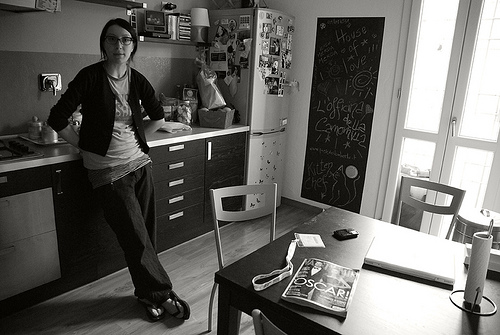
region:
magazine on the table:
[286, 242, 358, 319]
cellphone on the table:
[332, 220, 357, 244]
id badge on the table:
[241, 221, 330, 298]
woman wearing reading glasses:
[100, 30, 141, 57]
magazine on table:
[268, 240, 370, 334]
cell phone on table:
[327, 213, 373, 253]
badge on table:
[256, 219, 338, 304]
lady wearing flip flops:
[130, 266, 201, 332]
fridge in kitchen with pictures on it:
[210, 0, 320, 222]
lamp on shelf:
[188, 1, 221, 46]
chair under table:
[196, 166, 304, 279]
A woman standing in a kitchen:
[0, 0, 496, 333]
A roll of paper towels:
[460, 227, 495, 309]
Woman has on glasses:
[92, 12, 137, 67]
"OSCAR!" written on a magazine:
[290, 270, 350, 301]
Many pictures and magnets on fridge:
[201, 6, 292, 101]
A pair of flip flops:
[140, 285, 195, 325]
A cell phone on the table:
[325, 220, 360, 245]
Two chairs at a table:
[200, 170, 495, 330]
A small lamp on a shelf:
[185, 0, 215, 50]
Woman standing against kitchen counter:
[50, 15, 189, 326]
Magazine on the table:
[280, 253, 361, 323]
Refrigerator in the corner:
[196, 2, 300, 217]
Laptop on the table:
[360, 225, 468, 293]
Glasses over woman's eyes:
[100, 32, 136, 49]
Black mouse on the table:
[333, 227, 360, 241]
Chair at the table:
[395, 174, 465, 239]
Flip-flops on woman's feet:
[143, 294, 198, 323]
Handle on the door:
[446, 113, 460, 144]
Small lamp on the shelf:
[190, 4, 212, 43]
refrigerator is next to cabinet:
[204, 8, 295, 212]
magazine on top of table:
[213, 205, 498, 334]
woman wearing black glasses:
[45, 18, 192, 323]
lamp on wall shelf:
[135, 3, 212, 48]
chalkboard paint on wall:
[290, 0, 402, 218]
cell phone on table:
[215, 205, 498, 334]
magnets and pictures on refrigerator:
[203, 8, 293, 211]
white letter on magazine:
[292, 275, 307, 286]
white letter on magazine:
[301, 275, 316, 290]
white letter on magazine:
[313, 280, 328, 290]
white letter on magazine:
[325, 285, 337, 297]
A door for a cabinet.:
[198, 132, 251, 185]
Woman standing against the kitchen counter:
[48, 15, 193, 329]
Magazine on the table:
[283, 256, 360, 319]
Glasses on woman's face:
[103, 32, 133, 48]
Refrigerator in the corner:
[204, 7, 294, 215]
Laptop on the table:
[365, 224, 460, 291]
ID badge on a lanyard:
[251, 228, 324, 291]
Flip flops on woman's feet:
[147, 288, 189, 323]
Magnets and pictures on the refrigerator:
[256, 8, 296, 97]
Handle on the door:
[445, 113, 457, 132]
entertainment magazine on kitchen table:
[274, 244, 362, 321]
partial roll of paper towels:
[454, 217, 499, 321]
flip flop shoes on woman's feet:
[129, 279, 188, 334]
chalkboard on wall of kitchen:
[294, 29, 371, 214]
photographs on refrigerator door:
[199, 29, 293, 101]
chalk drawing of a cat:
[313, 160, 360, 210]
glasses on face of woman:
[97, 29, 138, 54]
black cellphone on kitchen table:
[327, 221, 367, 249]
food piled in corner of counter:
[155, 64, 243, 138]